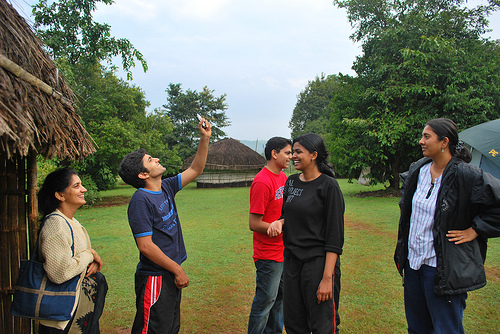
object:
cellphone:
[194, 112, 207, 130]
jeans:
[248, 259, 284, 334]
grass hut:
[182, 137, 266, 188]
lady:
[10, 168, 108, 334]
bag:
[10, 214, 109, 332]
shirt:
[249, 166, 284, 262]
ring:
[87, 265, 91, 267]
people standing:
[247, 133, 345, 333]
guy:
[249, 136, 292, 332]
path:
[343, 215, 500, 281]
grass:
[197, 189, 236, 256]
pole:
[8, 135, 19, 334]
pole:
[0, 143, 39, 334]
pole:
[17, 140, 28, 261]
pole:
[27, 147, 38, 260]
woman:
[267, 133, 345, 334]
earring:
[442, 148, 445, 152]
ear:
[442, 137, 449, 149]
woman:
[394, 118, 500, 334]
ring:
[316, 290, 318, 295]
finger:
[317, 288, 333, 304]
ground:
[40, 179, 500, 334]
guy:
[118, 112, 211, 334]